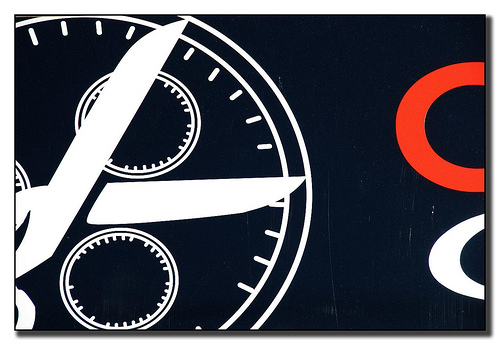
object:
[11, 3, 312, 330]
shape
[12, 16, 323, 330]
gauge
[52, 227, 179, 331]
gauge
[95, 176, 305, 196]
edge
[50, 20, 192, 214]
blades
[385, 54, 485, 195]
red curve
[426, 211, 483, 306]
white curve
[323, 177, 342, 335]
line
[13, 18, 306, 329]
scissors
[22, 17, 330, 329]
stencil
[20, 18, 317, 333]
clock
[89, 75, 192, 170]
hash marks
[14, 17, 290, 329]
hash marks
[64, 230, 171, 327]
hash marks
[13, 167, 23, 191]
hash marks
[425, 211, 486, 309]
line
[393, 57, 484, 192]
c shape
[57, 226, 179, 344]
circle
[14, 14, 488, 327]
picture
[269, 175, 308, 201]
tip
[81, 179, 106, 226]
shadow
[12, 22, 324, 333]
circle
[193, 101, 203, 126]
lines